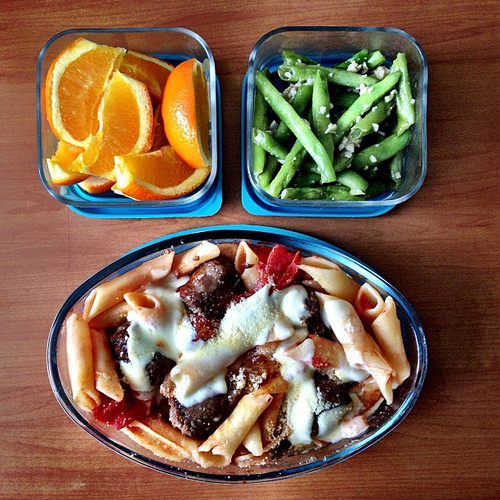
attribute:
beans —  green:
[252, 50, 418, 199]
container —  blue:
[243, 24, 428, 207]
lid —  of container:
[238, 49, 397, 217]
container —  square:
[44, 20, 221, 213]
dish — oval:
[41, 218, 435, 492]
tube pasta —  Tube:
[65, 313, 102, 417]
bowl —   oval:
[41, 217, 438, 491]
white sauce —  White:
[120, 281, 352, 428]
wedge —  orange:
[160, 57, 211, 167]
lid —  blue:
[64, 205, 226, 222]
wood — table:
[1, 0, 498, 500]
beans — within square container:
[256, 59, 401, 189]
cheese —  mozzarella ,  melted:
[129, 221, 378, 374]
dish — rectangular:
[235, 18, 433, 227]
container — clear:
[235, 20, 438, 221]